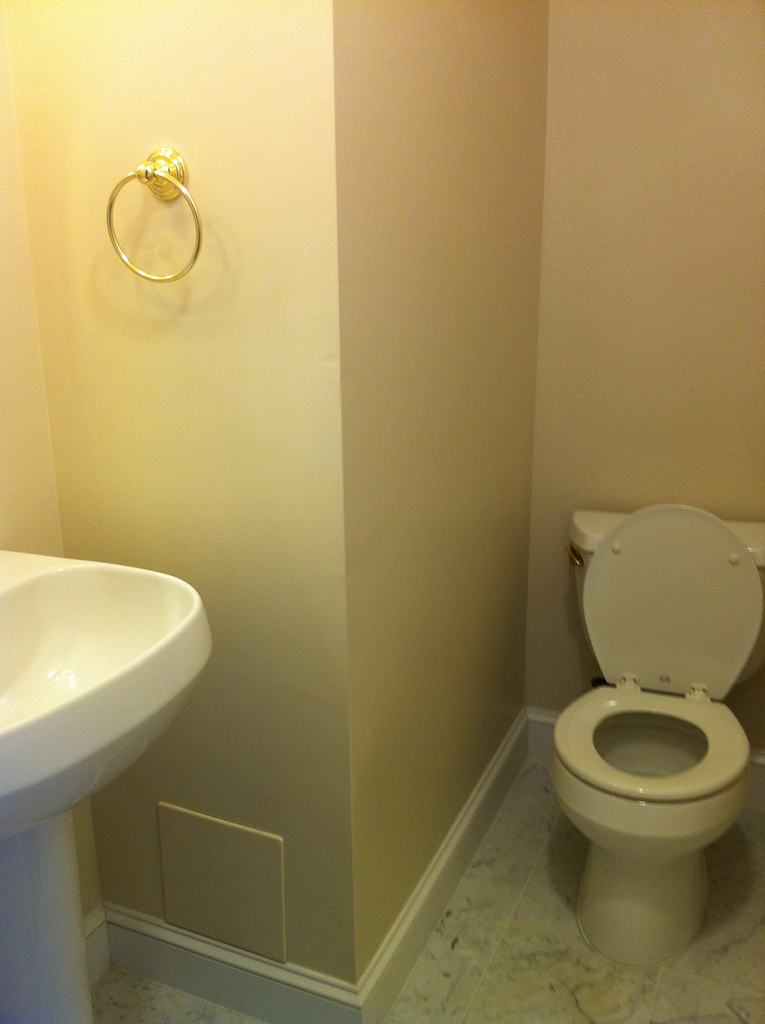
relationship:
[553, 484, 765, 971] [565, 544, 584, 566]
toilet with fush lever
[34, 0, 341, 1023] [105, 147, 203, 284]
beige wall with a gold holder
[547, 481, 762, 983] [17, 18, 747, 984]
toilet in bathroom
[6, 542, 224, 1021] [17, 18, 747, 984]
sink in bathroom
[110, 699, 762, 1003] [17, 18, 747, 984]
tile in bathroom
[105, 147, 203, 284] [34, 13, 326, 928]
gold holder on wall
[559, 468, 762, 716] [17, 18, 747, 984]
toilet lid in bathroom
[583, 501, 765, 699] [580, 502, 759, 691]
toilet lid behind toilet lid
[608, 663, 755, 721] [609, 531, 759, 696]
hinges at toilet lid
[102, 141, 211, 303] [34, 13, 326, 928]
gold holder on wall